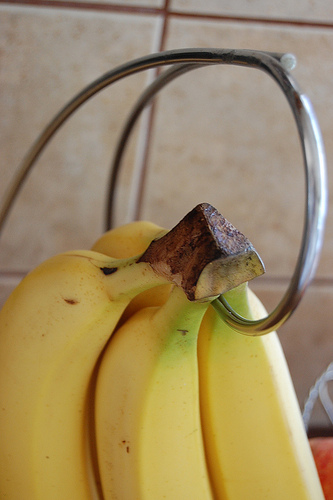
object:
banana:
[200, 276, 325, 498]